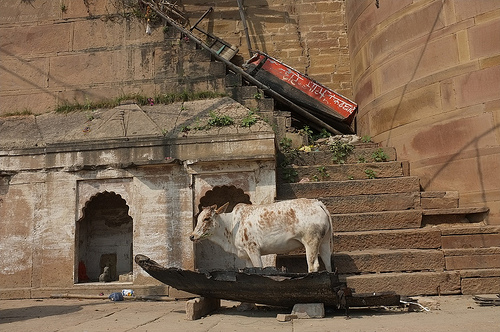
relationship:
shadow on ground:
[9, 291, 94, 324] [5, 297, 492, 329]